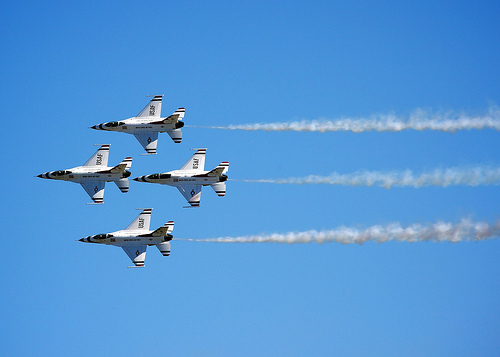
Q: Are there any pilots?
A: No, there are no pilots.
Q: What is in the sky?
A: The jet is in the sky.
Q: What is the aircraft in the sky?
A: The aircraft is a jet.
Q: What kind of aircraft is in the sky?
A: The aircraft is a jet.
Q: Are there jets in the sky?
A: Yes, there is a jet in the sky.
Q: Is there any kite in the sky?
A: No, there is a jet in the sky.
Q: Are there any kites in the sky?
A: No, there is a jet in the sky.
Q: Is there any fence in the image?
A: No, there are no fences.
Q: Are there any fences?
A: No, there are no fences.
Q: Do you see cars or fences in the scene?
A: No, there are no fences or cars.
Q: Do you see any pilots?
A: No, there are no pilots.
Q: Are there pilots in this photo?
A: No, there are no pilots.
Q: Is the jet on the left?
A: Yes, the jet is on the left of the image.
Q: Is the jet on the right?
A: No, the jet is on the left of the image.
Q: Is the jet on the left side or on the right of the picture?
A: The jet is on the left of the image.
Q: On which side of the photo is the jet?
A: The jet is on the left of the image.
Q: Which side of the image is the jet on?
A: The jet is on the left of the image.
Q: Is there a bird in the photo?
A: No, there are no birds.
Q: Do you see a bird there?
A: No, there are no birds.